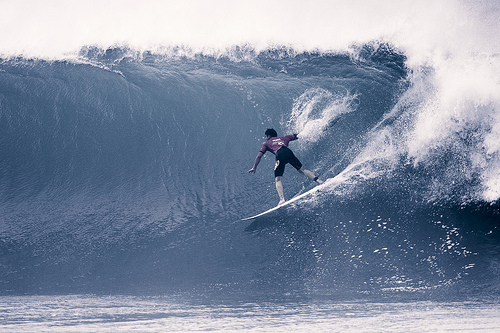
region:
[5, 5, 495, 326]
Huge whitecapped wave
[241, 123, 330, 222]
Man on a surfboard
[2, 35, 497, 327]
Surfboarder riding a wave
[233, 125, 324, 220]
Surfboarder with hand inside a wave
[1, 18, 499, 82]
White crest of a wave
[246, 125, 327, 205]
Man playing in the water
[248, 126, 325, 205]
Back of a person with black hair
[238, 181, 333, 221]
Light colored surf board in the water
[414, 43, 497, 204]
Whitewater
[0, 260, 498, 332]
Trough of a wave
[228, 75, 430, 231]
man surfing in ocean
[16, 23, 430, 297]
very large wave about to crash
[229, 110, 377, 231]
person with arm's out for balance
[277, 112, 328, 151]
man's left arm in the wall of wave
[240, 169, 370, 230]
white surfboard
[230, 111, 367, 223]
man wearing a black and red wet suit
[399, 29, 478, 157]
white ocean spray from surfer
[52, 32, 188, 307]
wall of very big wave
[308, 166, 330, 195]
strap used to attach man to surfboard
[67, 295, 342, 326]
calm ocean water before the wave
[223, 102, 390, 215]
a surfer riding a wave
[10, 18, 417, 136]
a wave just starting to crest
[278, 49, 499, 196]
wave breaking behind a surfer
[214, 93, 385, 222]
surfer riding a breaking wave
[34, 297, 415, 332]
calm ocean water before the wave breaks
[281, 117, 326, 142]
surfer touching a wave as he rides along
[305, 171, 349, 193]
surfboard tethered to the right ankle of surfer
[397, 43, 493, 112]
water spray from a breaking wave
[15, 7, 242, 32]
clear skies over the ocean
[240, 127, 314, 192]
surfer wearing a purple and black wet suit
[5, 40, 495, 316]
surfer on large wall of wave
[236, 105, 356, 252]
surfer slanting downwards on board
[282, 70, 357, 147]
circle of white water formed by arm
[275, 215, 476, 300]
dots of white water on wave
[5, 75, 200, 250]
deeper blue of curve in wave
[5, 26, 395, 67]
ruffled edge on top of wave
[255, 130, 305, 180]
surfer in purple and black outfit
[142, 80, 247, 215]
vertical ripples along wave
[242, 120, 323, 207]
arms and legs spread apart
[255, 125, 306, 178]
white writing and design on clothing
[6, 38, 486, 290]
wall of wave surfer is surfing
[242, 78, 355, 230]
surfer sticking his hand in wave wall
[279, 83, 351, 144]
white foam created by surfer's hand in wave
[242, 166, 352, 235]
surfboard cutting through wave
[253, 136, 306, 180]
purple and black wetsuit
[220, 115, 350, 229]
surfer standing on surfboard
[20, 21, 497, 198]
white foam of wave being ridden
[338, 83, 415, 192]
path surfboard cut in wave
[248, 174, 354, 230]
white surfboard being ridden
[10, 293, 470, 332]
calm sea in front of wave